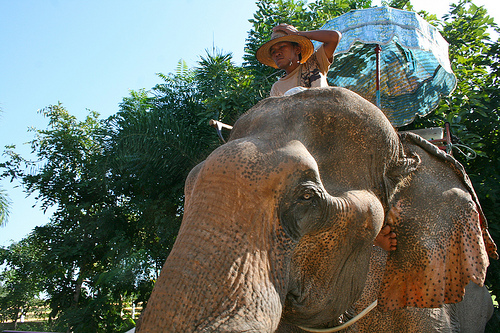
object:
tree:
[0, 2, 500, 333]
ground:
[446, 131, 477, 161]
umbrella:
[309, 7, 456, 128]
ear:
[377, 130, 497, 313]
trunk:
[133, 211, 291, 333]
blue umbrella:
[311, 7, 458, 129]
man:
[253, 23, 343, 97]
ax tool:
[205, 119, 235, 144]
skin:
[293, 255, 368, 329]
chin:
[294, 237, 333, 320]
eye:
[300, 191, 317, 200]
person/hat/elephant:
[137, 23, 500, 333]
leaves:
[95, 99, 152, 128]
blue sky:
[10, 0, 197, 95]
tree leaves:
[38, 101, 67, 126]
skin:
[316, 136, 365, 186]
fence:
[3, 295, 141, 322]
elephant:
[135, 85, 500, 333]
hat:
[254, 22, 314, 68]